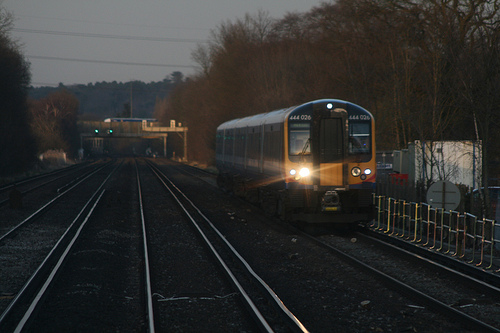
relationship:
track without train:
[5, 163, 122, 331] [215, 99, 376, 228]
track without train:
[134, 159, 307, 331] [215, 99, 376, 228]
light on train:
[289, 167, 310, 176] [215, 99, 376, 228]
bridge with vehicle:
[75, 118, 189, 158] [98, 112, 155, 124]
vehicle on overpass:
[102, 115, 157, 128] [72, 117, 187, 159]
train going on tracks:
[196, 94, 403, 230] [101, 159, 298, 322]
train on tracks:
[215, 99, 376, 228] [13, 160, 255, 330]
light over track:
[104, 125, 115, 137] [1, 150, 126, 330]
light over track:
[92, 127, 99, 133] [1, 150, 126, 330]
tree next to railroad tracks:
[389, 0, 499, 202] [161, 155, 500, 332]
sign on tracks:
[426, 177, 465, 215] [6, 152, 497, 332]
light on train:
[295, 165, 312, 177] [210, 99, 378, 238]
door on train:
[316, 120, 343, 189] [215, 99, 376, 228]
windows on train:
[294, 120, 374, 161] [215, 99, 376, 228]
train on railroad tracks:
[215, 99, 376, 228] [161, 155, 500, 332]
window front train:
[286, 132, 308, 153] [171, 73, 401, 249]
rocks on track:
[294, 250, 361, 313] [174, 246, 406, 296]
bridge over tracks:
[75, 103, 193, 159] [126, 212, 311, 328]